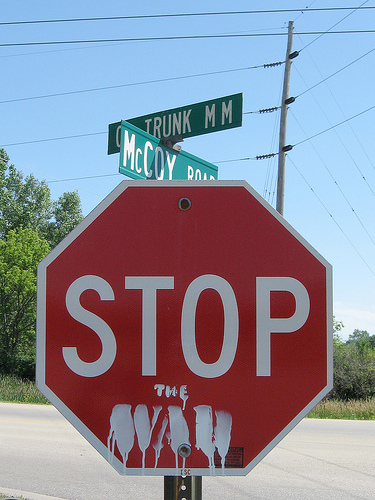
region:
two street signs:
[67, 81, 268, 196]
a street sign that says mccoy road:
[117, 133, 223, 201]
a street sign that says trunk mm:
[103, 96, 243, 149]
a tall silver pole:
[266, 14, 302, 215]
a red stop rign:
[30, 160, 348, 498]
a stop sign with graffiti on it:
[31, 157, 349, 498]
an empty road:
[0, 400, 364, 498]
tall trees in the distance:
[1, 149, 78, 409]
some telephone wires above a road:
[5, 6, 291, 183]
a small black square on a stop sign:
[208, 447, 253, 472]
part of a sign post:
[156, 407, 171, 418]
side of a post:
[137, 441, 153, 460]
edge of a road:
[15, 468, 34, 479]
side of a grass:
[319, 385, 342, 413]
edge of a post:
[235, 466, 241, 479]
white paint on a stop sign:
[106, 384, 234, 477]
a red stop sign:
[34, 179, 335, 477]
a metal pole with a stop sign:
[163, 475, 203, 498]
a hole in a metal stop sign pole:
[179, 484, 186, 490]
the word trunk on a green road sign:
[144, 108, 194, 136]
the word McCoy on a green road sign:
[122, 129, 176, 179]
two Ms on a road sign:
[201, 100, 233, 128]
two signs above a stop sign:
[107, 92, 243, 179]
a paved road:
[0, 401, 373, 499]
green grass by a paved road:
[1, 371, 374, 419]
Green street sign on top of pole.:
[120, 106, 254, 141]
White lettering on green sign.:
[118, 106, 249, 155]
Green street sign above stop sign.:
[122, 136, 238, 185]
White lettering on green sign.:
[127, 146, 214, 186]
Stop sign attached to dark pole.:
[139, 430, 214, 498]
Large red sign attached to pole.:
[65, 218, 301, 447]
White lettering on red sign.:
[59, 273, 309, 375]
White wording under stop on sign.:
[110, 369, 225, 456]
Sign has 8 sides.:
[31, 245, 329, 467]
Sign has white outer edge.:
[32, 253, 353, 494]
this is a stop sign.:
[51, 179, 308, 469]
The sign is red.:
[18, 159, 326, 401]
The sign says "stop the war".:
[60, 264, 312, 461]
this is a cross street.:
[97, 88, 240, 209]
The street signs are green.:
[108, 93, 223, 199]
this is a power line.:
[209, 6, 332, 204]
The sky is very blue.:
[47, 25, 254, 103]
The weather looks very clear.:
[20, 33, 265, 120]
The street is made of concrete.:
[286, 453, 372, 498]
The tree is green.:
[2, 196, 62, 261]